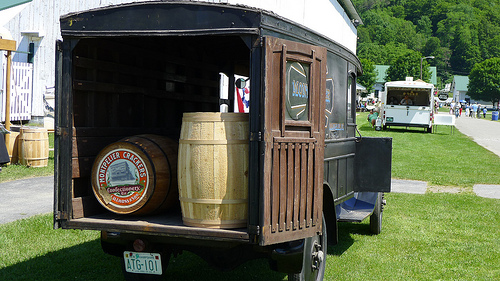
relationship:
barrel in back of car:
[176, 110, 252, 228] [51, 0, 392, 281]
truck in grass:
[372, 72, 433, 149] [397, 128, 453, 173]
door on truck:
[71, 74, 280, 231] [195, 63, 405, 273]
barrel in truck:
[176, 110, 252, 228] [284, 127, 345, 235]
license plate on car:
[100, 251, 170, 274] [51, 0, 392, 281]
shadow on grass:
[1, 236, 295, 281] [23, 226, 68, 263]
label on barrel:
[103, 156, 137, 202] [79, 141, 171, 209]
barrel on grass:
[15, 129, 53, 186] [7, 156, 26, 183]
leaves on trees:
[380, 52, 431, 80] [378, 49, 449, 89]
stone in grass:
[406, 170, 430, 202] [400, 202, 446, 238]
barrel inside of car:
[176, 108, 251, 229] [51, 0, 393, 279]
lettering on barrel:
[95, 150, 145, 180] [87, 129, 177, 216]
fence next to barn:
[5, 59, 33, 124] [2, 0, 362, 137]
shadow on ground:
[1, 236, 291, 277] [4, 216, 96, 275]